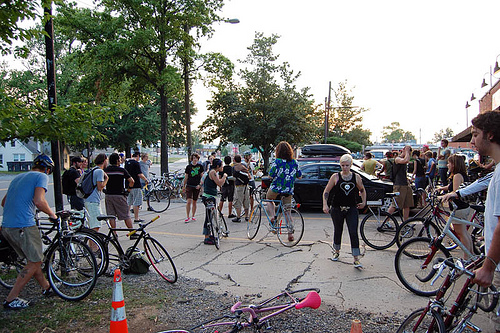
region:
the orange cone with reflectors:
[108, 268, 130, 331]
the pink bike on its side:
[180, 285, 321, 332]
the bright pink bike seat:
[296, 290, 321, 310]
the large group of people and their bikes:
[1, 110, 499, 329]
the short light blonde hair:
[338, 153, 354, 165]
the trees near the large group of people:
[1, 0, 499, 332]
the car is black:
[282, 154, 399, 214]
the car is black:
[237, 148, 397, 235]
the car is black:
[250, 151, 398, 233]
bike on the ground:
[188, 277, 320, 331]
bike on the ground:
[197, 283, 337, 330]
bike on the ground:
[195, 268, 325, 331]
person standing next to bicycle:
[245, 139, 307, 248]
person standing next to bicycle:
[0, 153, 97, 311]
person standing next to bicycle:
[125, 149, 170, 222]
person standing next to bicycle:
[397, 154, 483, 264]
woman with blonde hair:
[323, 152, 369, 269]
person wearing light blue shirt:
[1, 150, 57, 306]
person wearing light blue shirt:
[78, 153, 106, 260]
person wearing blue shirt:
[262, 137, 298, 249]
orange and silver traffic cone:
[103, 265, 129, 331]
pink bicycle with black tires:
[181, 283, 326, 332]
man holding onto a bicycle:
[0, 150, 95, 316]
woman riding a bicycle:
[244, 139, 306, 246]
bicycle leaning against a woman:
[199, 156, 232, 251]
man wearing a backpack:
[75, 150, 110, 259]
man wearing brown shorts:
[381, 143, 413, 235]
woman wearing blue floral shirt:
[263, 139, 300, 243]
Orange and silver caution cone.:
[107, 269, 129, 332]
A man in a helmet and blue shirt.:
[0, 154, 57, 309]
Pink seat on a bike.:
[296, 290, 321, 310]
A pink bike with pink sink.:
[187, 286, 321, 332]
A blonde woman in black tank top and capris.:
[321, 152, 368, 269]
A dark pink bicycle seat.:
[292, 290, 321, 310]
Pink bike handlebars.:
[228, 300, 260, 331]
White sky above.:
[1, 1, 498, 140]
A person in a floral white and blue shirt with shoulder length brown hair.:
[262, 144, 301, 243]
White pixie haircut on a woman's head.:
[340, 154, 352, 166]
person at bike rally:
[257, 139, 302, 247]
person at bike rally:
[321, 138, 379, 265]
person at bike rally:
[200, 159, 240, 236]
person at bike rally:
[181, 152, 226, 273]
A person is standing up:
[261, 135, 309, 248]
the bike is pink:
[150, 285, 320, 330]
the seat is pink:
[295, 290, 321, 309]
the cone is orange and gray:
[109, 265, 129, 331]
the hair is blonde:
[338, 153, 352, 166]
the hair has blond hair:
[322, 151, 367, 268]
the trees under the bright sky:
[0, 0, 499, 331]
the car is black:
[260, 160, 420, 209]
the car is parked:
[260, 160, 417, 212]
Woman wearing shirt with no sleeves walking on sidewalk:
[314, 148, 374, 278]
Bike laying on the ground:
[189, 283, 338, 328]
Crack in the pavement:
[286, 275, 388, 287]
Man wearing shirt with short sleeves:
[3, 145, 57, 312]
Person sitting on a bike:
[241, 137, 313, 251]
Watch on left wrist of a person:
[453, 188, 463, 197]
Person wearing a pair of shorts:
[179, 150, 206, 224]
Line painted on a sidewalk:
[104, 221, 464, 256]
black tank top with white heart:
[331, 169, 360, 210]